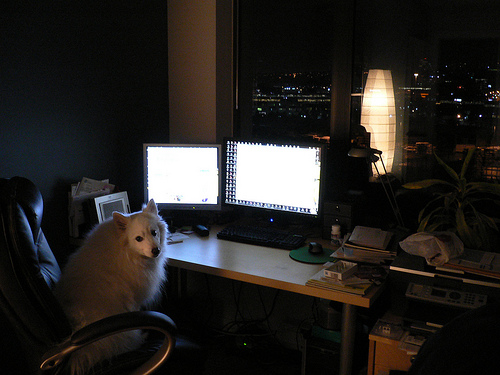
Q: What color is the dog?
A: White.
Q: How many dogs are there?
A: One.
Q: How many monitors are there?
A: Two.